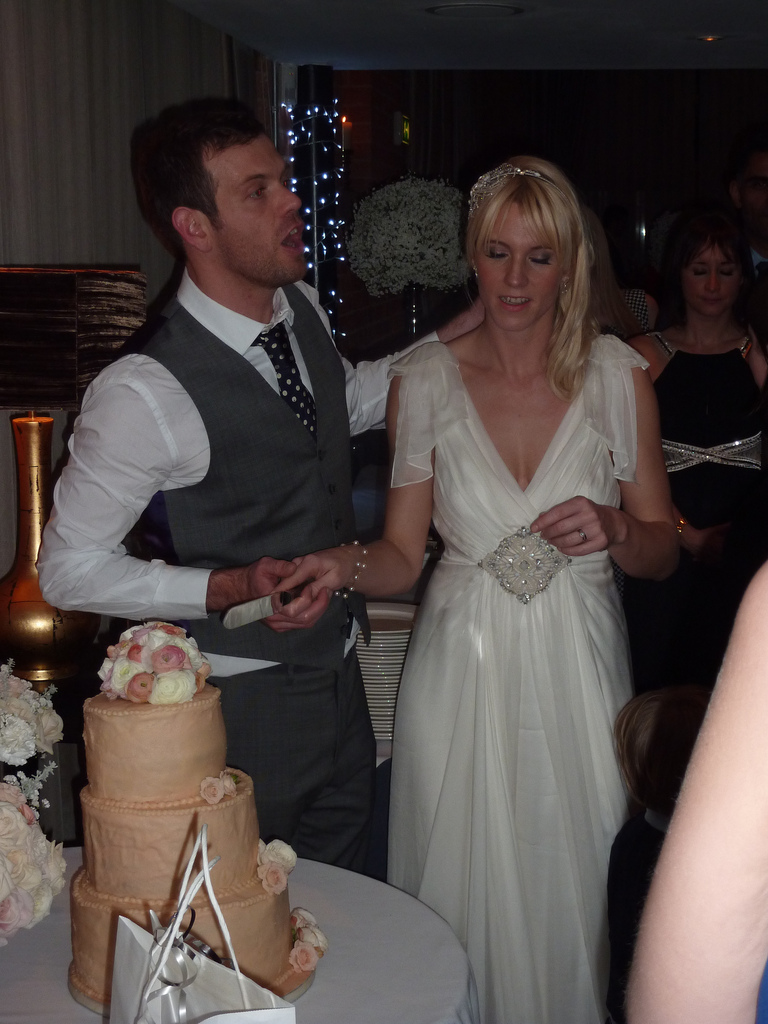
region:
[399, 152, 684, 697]
BRIDE IN WHITE WEDDING DRESS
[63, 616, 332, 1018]
PEACH COLORED WEDDING CAKE WITH FLOWERS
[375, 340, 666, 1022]
WHITE WEDDING DRESS ON BRIDE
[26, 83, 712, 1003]
BRIDE AND GROOM CUTTING WEDDING CAKE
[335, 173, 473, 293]
TREE WITH WHITE FLOWERS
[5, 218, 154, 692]
ANTIQUED DECORATIVE GOLD LAMP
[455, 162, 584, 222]
TIARA ON BLONDE WOMAN'S HEAD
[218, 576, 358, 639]
COUPLE HOLDING KNIFE TO CUT CAKE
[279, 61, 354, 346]
DECORATIVE WHITE LIGHTS ON WIRE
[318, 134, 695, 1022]
woman has white dress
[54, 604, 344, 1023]
the cake is chocolate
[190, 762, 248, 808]
flowers over the cake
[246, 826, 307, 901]
flowers over the cake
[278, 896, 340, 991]
flowers over the cake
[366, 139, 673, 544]
the woman is blonde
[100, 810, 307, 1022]
the bay is white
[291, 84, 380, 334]
the lights are color blue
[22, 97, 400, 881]
man has a gray vest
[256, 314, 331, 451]
the tie id black and white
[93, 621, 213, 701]
pink and white flowers on cake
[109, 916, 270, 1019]
white paper bag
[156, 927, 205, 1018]
curly silver ribbon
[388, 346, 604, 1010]
long white wedding gown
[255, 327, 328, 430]
dark tie with white dots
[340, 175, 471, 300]
bouquet of small white flowers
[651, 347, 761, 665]
long black gown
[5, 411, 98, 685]
tall gold vase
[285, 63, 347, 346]
black pole with white lights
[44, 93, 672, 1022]
man and woman holding hands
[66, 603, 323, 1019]
brown cake with a floral decoration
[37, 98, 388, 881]
man wearing a dotted tie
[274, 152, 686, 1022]
woman wearing a dress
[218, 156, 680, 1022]
woman holding a knife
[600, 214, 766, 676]
woman has her eyes closed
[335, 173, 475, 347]
decorative bush in a vase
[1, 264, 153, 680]
brown and gold lamp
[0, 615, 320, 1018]
floral arrangement near the cake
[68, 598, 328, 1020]
a brown 3 tiered cake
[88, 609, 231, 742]
a bunch of flowers on a cake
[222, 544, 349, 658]
a couple holding the same knife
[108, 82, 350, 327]
a white male with shaved beard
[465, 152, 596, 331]
a female with her eyes closed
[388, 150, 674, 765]
a female wearing a white gown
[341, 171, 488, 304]
a big ball of flowers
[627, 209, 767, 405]
a lady wearing a black dress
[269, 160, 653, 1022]
a person is standing up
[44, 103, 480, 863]
a person is standing up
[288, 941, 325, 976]
A flower on a cake.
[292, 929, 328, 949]
A flower on a cake.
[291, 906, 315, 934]
A flower on a cake.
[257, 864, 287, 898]
A flower on a cake.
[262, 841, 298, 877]
A flower on a cake.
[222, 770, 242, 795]
A flower on a cake.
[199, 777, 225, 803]
A flower on a cake.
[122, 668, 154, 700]
A flower on a cake.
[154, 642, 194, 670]
A flower on a cake.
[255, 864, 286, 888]
A flower on a cake.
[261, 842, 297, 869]
A flower on a cake.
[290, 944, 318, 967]
A flower on a cake.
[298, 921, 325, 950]
A flower on a cake.